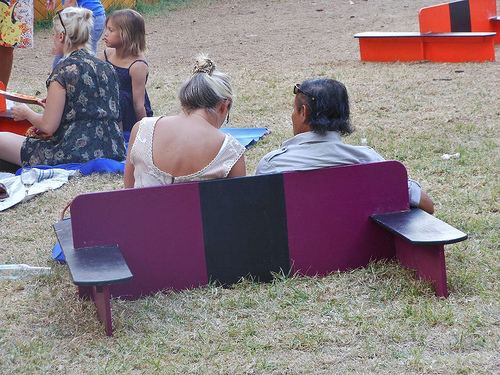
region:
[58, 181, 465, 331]
A seat is made of wood.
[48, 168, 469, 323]
The seat is black and purple.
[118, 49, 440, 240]
Two people are sitting side by side.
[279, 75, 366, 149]
The man has glasses on his head.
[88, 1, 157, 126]
The little girl is wearing a dress.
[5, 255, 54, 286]
A glass bottle is on the ground.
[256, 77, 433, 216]
sitting enjoying a picnic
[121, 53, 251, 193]
sitting enjoying a picnic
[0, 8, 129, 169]
sitting enjoying a picnic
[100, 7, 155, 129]
sitting enjoying a picnic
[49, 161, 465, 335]
odd looking ground sofa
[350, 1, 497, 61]
odd looking ground sofa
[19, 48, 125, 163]
floral shirt on older lady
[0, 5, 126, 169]
older lady is eating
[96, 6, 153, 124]
child with a blue tank on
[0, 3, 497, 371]
nearly dead yellow grass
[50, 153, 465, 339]
a very low bench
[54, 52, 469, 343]
a woman on a very low bench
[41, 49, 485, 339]
a man on a very low bench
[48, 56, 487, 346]
a couple on a very low bench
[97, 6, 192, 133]
a little girl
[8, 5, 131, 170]
a woman sitting down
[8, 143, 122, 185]
a blue blanket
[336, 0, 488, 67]
empty benches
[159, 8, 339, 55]
grass field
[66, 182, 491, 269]
purple and black bench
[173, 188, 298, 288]
black stripe on bench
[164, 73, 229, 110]
woman has blonde hair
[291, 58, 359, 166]
person has dark hair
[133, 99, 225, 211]
woman has white shirt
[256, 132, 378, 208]
person has blue shirt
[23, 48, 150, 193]
woman has green dress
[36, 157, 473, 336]
a very low bench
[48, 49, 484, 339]
a lady on a very low bench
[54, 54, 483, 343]
a man on a very low bench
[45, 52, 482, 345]
a couple on a very low bench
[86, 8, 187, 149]
a little girl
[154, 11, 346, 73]
a grassy field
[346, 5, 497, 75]
empty benches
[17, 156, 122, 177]
a blue blanket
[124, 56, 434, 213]
back of seated couple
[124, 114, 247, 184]
back of sleeveless top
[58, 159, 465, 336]
bench with no seat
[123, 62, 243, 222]
A person is sitting down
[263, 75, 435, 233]
A person is sitting down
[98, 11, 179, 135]
A person is sitting down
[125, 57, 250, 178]
woman sitting down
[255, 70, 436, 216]
man sitting down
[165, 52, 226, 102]
blonde hair of woman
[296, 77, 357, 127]
black hair of man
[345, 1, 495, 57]
red seat on the grass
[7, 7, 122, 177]
woman in blue sitting down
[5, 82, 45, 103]
pizza in womans hand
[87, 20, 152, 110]
little girl sitting down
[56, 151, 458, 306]
purple and black seat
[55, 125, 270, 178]
blue colored blanket on ground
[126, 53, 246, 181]
blonde woman sitting down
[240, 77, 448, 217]
man with dark hair sitting on grass